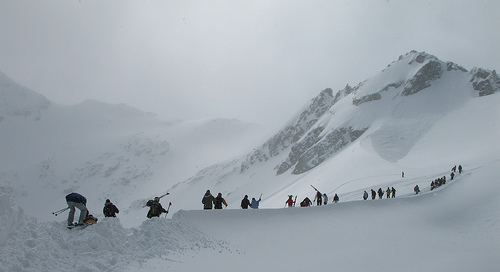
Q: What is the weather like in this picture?
A: It is foggy.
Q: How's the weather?
A: It is foggy.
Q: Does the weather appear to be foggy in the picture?
A: Yes, it is foggy.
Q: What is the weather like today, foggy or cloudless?
A: It is foggy.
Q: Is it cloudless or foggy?
A: It is foggy.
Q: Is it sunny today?
A: No, it is foggy.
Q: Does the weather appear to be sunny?
A: No, it is foggy.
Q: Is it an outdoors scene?
A: Yes, it is outdoors.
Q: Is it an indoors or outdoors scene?
A: It is outdoors.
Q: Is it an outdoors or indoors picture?
A: It is outdoors.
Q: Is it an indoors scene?
A: No, it is outdoors.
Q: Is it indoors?
A: No, it is outdoors.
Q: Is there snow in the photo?
A: Yes, there is snow.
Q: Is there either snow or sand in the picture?
A: Yes, there is snow.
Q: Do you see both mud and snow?
A: No, there is snow but no mud.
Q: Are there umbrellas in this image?
A: No, there are no umbrellas.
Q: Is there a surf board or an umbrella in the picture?
A: No, there are no umbrellas or surfboards.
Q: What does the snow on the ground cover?
A: The snow covers the mountain.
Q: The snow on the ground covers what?
A: The snow covers the mountain.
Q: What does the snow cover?
A: The snow covers the mountain.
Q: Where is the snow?
A: The snow is on the ground.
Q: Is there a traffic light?
A: No, there are no traffic lights.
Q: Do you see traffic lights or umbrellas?
A: No, there are no traffic lights or umbrellas.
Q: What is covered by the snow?
A: The mountain is covered by the snow.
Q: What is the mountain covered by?
A: The mountain is covered by the snow.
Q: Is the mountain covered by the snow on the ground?
A: Yes, the mountain is covered by the snow.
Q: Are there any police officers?
A: No, there are no police officers.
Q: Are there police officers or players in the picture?
A: No, there are no police officers or players.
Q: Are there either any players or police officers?
A: No, there are no police officers or players.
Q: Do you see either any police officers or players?
A: No, there are no police officers or players.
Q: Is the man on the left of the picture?
A: Yes, the man is on the left of the image.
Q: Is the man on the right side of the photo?
A: No, the man is on the left of the image.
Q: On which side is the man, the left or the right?
A: The man is on the left of the image.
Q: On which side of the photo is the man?
A: The man is on the left of the image.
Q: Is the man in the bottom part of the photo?
A: Yes, the man is in the bottom of the image.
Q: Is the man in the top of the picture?
A: No, the man is in the bottom of the image.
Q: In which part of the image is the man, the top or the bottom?
A: The man is in the bottom of the image.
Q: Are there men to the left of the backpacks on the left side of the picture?
A: Yes, there is a man to the left of the backpacks.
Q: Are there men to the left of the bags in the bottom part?
A: Yes, there is a man to the left of the backpacks.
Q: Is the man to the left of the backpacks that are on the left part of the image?
A: Yes, the man is to the left of the backpacks.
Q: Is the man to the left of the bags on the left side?
A: Yes, the man is to the left of the backpacks.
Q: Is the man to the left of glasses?
A: No, the man is to the left of the backpacks.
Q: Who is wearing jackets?
A: The man is wearing jackets.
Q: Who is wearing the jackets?
A: The man is wearing jackets.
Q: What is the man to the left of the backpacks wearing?
A: The man is wearing jackets.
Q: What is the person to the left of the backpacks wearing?
A: The man is wearing jackets.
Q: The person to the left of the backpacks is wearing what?
A: The man is wearing jackets.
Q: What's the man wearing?
A: The man is wearing jackets.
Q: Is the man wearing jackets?
A: Yes, the man is wearing jackets.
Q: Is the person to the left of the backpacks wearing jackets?
A: Yes, the man is wearing jackets.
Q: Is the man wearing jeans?
A: No, the man is wearing jackets.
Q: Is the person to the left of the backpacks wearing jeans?
A: No, the man is wearing jackets.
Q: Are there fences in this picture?
A: No, there are no fences.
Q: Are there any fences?
A: No, there are no fences.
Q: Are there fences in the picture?
A: No, there are no fences.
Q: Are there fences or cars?
A: No, there are no fences or cars.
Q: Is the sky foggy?
A: Yes, the sky is foggy.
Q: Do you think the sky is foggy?
A: Yes, the sky is foggy.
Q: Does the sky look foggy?
A: Yes, the sky is foggy.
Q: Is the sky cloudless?
A: No, the sky is foggy.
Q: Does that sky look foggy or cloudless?
A: The sky is foggy.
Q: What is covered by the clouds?
A: The sky is covered by the clouds.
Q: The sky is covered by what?
A: The sky is covered by the clouds.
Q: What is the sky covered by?
A: The sky is covered by the clouds.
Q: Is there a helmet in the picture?
A: No, there are no helmets.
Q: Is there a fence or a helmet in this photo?
A: No, there are no helmets or fences.